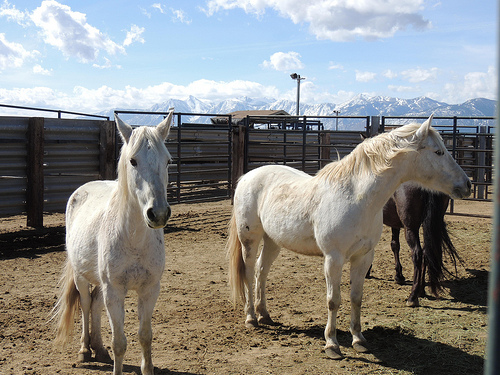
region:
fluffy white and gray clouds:
[1, 0, 499, 97]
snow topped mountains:
[0, 95, 497, 131]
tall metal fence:
[0, 98, 496, 229]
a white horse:
[43, 108, 173, 373]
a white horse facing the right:
[224, 116, 472, 359]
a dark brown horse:
[365, 185, 465, 305]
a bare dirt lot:
[3, 187, 492, 373]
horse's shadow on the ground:
[434, 260, 492, 316]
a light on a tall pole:
[287, 71, 304, 117]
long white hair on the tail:
[222, 207, 247, 311]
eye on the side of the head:
[431, 146, 448, 158]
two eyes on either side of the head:
[126, 153, 176, 170]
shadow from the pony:
[256, 304, 487, 374]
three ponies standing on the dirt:
[41, 108, 494, 373]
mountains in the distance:
[85, 95, 499, 137]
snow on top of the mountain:
[144, 85, 464, 118]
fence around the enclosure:
[2, 93, 499, 238]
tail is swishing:
[42, 265, 85, 360]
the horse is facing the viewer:
[55, 115, 173, 371]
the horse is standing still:
[60, 112, 185, 368]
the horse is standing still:
[225, 102, 470, 357]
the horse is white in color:
[47, 115, 187, 372]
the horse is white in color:
[223, 124, 453, 356]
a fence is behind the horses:
[10, 113, 495, 205]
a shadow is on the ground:
[276, 317, 496, 373]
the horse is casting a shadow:
[238, 115, 491, 368]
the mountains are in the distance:
[70, 95, 491, 140]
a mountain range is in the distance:
[74, 98, 499, 140]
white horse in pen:
[45, 98, 202, 372]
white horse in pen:
[239, 135, 424, 328]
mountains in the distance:
[159, 87, 446, 127]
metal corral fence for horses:
[55, 98, 375, 175]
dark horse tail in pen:
[392, 188, 467, 325]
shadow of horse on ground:
[277, 296, 468, 372]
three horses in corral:
[78, 118, 483, 317]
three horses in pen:
[57, 81, 462, 365]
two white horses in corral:
[62, 95, 453, 373]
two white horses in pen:
[85, 112, 462, 374]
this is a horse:
[46, 94, 212, 368]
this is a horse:
[215, 108, 487, 359]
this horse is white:
[26, 123, 234, 369]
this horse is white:
[209, 106, 474, 343]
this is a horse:
[349, 136, 486, 321]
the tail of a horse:
[209, 193, 263, 314]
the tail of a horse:
[46, 240, 94, 356]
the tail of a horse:
[411, 193, 475, 310]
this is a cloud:
[33, 0, 131, 75]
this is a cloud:
[158, 73, 281, 133]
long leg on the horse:
[70, 275, 93, 365]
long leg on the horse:
[90, 280, 110, 365]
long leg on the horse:
[96, 290, 126, 372]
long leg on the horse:
[130, 291, 155, 371]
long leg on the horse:
[232, 230, 257, 325]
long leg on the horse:
[320, 255, 340, 355]